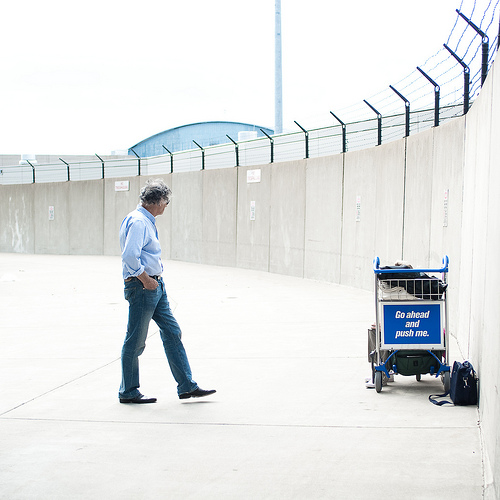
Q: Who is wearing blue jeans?
A: The man.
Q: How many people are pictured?
A: One.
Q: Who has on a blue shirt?
A: A man.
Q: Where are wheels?
A: Under a cart.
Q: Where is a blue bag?
A: On the ground.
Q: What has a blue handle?
A: The cart.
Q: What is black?
A: Man's shoes.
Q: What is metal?
A: The cart.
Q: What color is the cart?
A: Blue.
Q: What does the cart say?
A: Go ahead and push me.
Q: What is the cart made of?
A: Metal.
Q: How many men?
A: One.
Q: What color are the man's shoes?
A: Black.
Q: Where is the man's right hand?
A: In his pocket.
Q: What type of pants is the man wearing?
A: Blue jeans.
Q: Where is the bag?
A: The ground.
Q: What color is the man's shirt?
A: Light Blue.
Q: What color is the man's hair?
A: Gray.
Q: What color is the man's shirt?
A: Blue.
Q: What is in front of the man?
A: A cart.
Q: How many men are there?
A: One.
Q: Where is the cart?
A: In front of the man.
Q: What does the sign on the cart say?
A: Go ahead and push me.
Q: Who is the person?
A: A man.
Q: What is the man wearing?
A: Shirt and jeans.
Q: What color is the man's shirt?
A: Blue.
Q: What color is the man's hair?
A: Gray.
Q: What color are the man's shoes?
A: Black.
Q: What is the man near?
A: A cart.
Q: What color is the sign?
A: Blue.